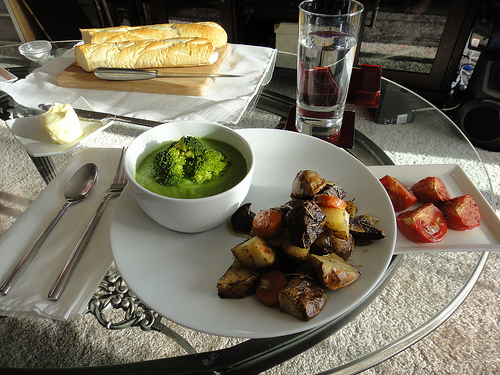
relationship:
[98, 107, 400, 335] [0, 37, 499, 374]
dishes on table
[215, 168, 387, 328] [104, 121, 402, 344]
beef stew on a plate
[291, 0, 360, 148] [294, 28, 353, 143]
glass of water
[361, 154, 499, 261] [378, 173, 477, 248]
side plate of tomatoes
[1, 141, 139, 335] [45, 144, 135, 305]
napkin has fork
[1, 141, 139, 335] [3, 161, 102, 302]
napkin has spoon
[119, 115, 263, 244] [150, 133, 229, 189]
soup cup has broccoli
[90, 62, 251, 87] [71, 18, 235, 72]
knife next to bread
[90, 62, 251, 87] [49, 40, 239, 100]
knife on breadboard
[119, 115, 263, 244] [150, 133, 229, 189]
soup bowl with broccoli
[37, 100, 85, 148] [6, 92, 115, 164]
butter on napkin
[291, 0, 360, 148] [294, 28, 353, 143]
glass has water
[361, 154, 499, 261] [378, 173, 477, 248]
side plate has tomatoes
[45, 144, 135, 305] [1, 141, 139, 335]
fork on a napkin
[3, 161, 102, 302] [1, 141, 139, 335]
spoon on a napkin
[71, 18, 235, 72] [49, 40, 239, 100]
bread on breadboard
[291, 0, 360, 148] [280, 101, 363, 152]
glass on a coaster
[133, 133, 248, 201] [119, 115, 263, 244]
broccoli soup in a bowl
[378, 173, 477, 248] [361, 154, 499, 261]
tomatoes are on a side plate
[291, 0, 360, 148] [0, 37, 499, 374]
glass on a table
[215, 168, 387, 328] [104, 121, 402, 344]
food on a plate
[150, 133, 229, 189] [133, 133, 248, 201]
broccoli in a soup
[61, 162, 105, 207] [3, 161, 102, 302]
top of a spoon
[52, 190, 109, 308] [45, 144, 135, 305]
handle of a fork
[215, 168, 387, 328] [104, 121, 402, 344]
vegatables are on a plate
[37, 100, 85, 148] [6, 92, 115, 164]
butter on a napkin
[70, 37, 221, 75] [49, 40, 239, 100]
loaf on breadboard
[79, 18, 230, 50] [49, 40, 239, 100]
loaf on breadboard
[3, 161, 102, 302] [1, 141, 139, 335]
spoon on napkin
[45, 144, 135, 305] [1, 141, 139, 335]
fork on napkin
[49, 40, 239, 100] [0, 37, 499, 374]
breadboard on table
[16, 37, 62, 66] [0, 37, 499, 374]
container on table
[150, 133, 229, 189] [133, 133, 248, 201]
broccoli in soup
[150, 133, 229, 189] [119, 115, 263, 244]
broccoli in bowl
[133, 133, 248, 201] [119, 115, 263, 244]
soup in bowl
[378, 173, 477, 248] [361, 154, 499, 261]
tomatoes are on a plate